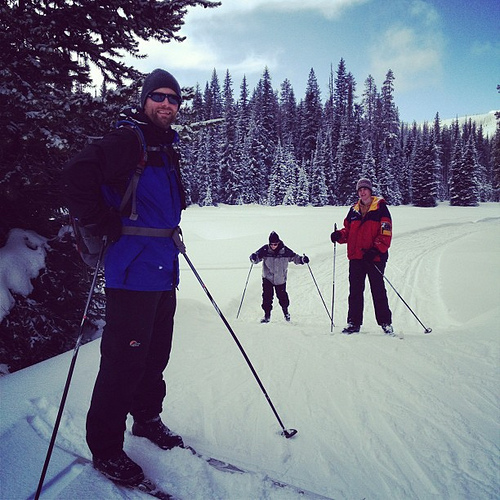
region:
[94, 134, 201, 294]
the jacket is blue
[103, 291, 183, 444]
the pants are black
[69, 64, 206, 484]
the man has a back pack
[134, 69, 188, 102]
the amrvin is blue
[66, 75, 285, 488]
the man has glasses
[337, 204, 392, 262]
the jacket is black and red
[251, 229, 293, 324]
the man is skiing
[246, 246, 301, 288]
the jacket is grey and black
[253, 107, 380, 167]
the trees have snow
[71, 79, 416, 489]
the people are three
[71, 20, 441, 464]
SKIIERS IN THE SNOW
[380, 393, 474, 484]
tracks in the snow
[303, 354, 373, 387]
snow on the ground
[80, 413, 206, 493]
feet on the skis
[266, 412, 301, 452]
pole in the snow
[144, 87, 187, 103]
glasses on the face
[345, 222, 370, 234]
the jacket is red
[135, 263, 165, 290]
the jacket is blue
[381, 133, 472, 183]
the trees are pine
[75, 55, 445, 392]
people in the snow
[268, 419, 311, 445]
bottom of pole in snow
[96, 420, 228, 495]
feet on the skis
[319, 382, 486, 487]
tracks in the snow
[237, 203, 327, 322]
child in the snow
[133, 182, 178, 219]
the jacket is blue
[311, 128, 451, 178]
the trees are pine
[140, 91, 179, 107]
goggles on the eyes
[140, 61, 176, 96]
hat on the head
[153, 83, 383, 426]
three people in the picture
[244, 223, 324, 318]
a yopung boy skirting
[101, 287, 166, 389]
pants are black in color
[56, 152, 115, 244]
bag is black in color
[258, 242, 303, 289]
jacket is white in color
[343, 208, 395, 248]
jacket is red in color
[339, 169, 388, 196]
the mavin is grey in color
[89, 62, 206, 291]
the man is smiling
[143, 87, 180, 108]
sunglasses worn by a man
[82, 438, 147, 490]
a boot in a cross-country ski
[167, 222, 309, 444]
a cross-country ski pole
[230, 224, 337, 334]
a man in a tan jacket cross-country skiing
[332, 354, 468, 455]
snow on the ground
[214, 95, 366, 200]
evergreen trees covered in snow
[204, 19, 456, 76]
sky with a few clouds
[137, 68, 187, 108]
a dark cap worn by a skiier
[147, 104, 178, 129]
the beard of a man skiing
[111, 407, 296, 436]
man is standing in snow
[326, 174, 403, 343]
a man wearing a red jacket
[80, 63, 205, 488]
a man wearing a blue jacket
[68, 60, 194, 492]
a man wearing sunglasses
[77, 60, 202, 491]
a man with a beard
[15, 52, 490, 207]
a line of pine trees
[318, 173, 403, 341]
a man wearing a red jacket with a yellow coll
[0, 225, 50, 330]
a clump of snow on the tree to the left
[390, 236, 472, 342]
ski tracks in the snow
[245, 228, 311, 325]
a person wearing a purple jacket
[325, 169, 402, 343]
a man wearing a red jacket and black pants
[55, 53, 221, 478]
a person is standing up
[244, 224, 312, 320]
a person is standing up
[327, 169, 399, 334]
a person is standing up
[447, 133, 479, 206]
a tree in a field